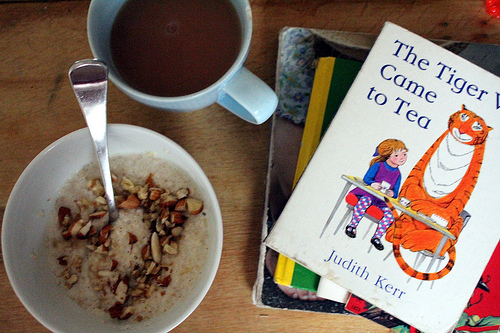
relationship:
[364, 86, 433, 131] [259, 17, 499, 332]
word in book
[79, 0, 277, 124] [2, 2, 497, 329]
cup sitting on table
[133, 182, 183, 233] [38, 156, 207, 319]
nuts on food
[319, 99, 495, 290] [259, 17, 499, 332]
picture on book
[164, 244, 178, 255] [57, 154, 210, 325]
pecans in oatmeal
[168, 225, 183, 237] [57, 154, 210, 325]
pecans in oatmeal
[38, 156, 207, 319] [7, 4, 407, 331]
food on table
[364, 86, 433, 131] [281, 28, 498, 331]
word are on book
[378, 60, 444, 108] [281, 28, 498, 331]
word on book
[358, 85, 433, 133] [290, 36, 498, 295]
word on book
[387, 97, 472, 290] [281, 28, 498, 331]
tiger on book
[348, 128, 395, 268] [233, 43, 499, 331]
girl on book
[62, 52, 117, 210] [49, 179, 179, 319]
spoon in oatmeal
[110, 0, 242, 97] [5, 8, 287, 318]
coffee on table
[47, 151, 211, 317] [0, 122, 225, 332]
oatmeal in bowl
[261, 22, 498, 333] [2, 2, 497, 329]
book are on table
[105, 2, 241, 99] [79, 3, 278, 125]
liquid in cup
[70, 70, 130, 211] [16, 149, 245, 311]
utensil in bowl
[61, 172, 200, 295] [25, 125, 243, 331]
food in bowl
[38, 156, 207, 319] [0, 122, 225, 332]
food in bowl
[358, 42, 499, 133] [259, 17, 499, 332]
title on book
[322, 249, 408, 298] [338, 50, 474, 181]
author on book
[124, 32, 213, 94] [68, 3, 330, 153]
coffee in cup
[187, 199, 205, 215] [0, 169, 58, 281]
nuts are in bowl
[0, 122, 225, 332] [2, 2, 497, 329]
bowl on table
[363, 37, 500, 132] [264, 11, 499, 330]
title on cover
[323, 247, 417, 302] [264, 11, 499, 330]
author on cover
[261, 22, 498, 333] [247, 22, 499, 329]
book on stack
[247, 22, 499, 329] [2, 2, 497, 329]
stack on table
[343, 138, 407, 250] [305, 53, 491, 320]
girl on book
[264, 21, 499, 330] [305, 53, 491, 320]
cover on book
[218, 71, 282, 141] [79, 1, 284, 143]
handle on mug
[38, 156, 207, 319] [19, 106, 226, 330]
food on bowl